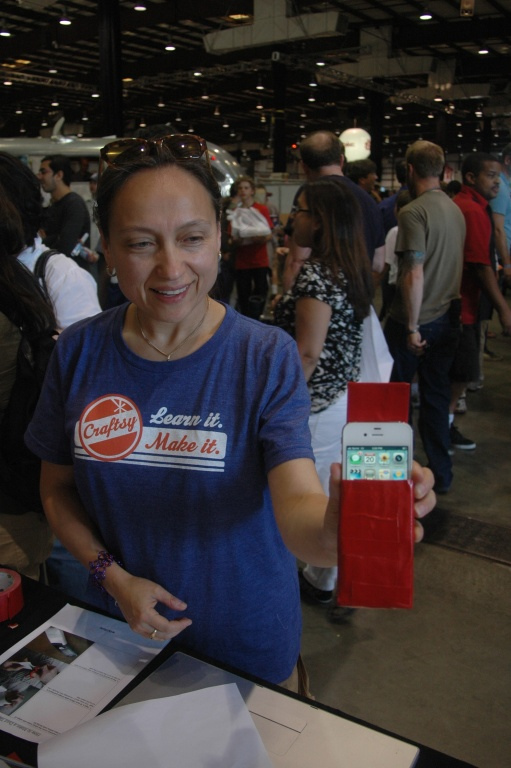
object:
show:
[335, 421, 415, 612]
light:
[165, 46, 176, 50]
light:
[134, 6, 146, 12]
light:
[420, 15, 433, 21]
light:
[478, 50, 489, 55]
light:
[475, 112, 482, 119]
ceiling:
[0, 0, 510, 173]